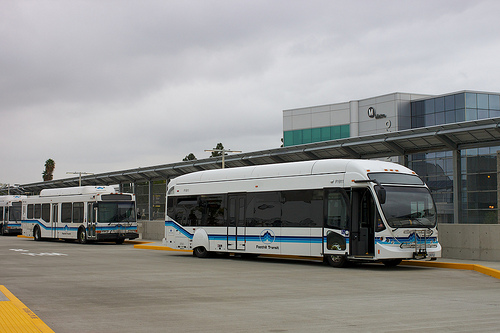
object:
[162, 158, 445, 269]
bus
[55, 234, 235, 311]
road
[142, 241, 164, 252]
sidewalk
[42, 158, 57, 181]
tree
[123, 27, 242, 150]
sky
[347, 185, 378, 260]
door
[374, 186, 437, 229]
windshield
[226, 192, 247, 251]
exit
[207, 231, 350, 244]
stripe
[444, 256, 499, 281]
curb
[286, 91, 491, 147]
building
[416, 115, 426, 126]
windows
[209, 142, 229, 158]
trees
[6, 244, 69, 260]
pavement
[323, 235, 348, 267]
wheels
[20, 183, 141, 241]
buses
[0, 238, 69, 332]
road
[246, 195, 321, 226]
windows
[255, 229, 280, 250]
logo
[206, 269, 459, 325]
concrete